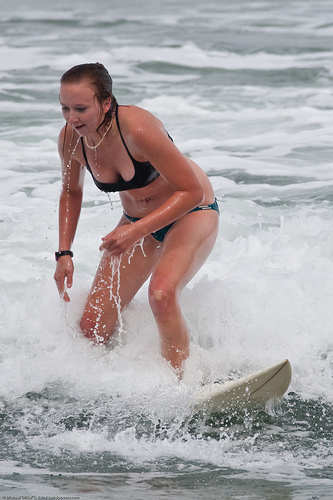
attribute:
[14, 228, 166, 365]
ocean wave — small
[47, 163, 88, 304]
arm — pictured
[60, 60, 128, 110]
hair — black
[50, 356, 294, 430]
surf board — white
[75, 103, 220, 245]
bikini — black, green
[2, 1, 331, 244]
water — gray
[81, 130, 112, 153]
necklace — white, beaded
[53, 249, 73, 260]
watch — black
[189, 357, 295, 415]
surfboard — brown, white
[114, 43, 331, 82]
wave — white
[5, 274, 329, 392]
wave — white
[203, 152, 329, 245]
wave — white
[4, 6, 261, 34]
wave — white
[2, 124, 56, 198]
wave — white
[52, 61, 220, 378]
woman — pictured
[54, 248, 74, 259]
watch — water proof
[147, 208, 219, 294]
thigh — pictured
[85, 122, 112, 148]
necklace — white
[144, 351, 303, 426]
board — white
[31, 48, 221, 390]
human — female